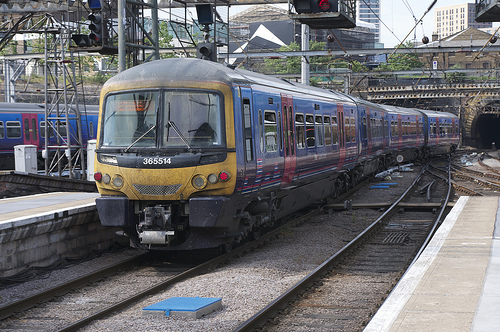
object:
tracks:
[260, 218, 438, 332]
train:
[93, 57, 463, 250]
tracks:
[338, 177, 440, 241]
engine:
[93, 57, 234, 251]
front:
[95, 57, 235, 251]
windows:
[101, 92, 222, 152]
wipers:
[123, 120, 195, 154]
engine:
[94, 57, 235, 243]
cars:
[93, 56, 463, 254]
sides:
[233, 80, 460, 195]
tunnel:
[459, 88, 500, 153]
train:
[87, 55, 465, 250]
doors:
[235, 86, 295, 194]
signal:
[288, 1, 356, 29]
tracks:
[74, 254, 377, 305]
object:
[142, 296, 222, 318]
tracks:
[0, 256, 368, 313]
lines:
[234, 147, 356, 195]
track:
[126, 199, 363, 330]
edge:
[393, 195, 463, 328]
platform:
[368, 195, 500, 323]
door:
[239, 87, 256, 195]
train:
[81, 57, 461, 262]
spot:
[92, 282, 108, 306]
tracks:
[338, 165, 499, 197]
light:
[94, 171, 124, 187]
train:
[88, 56, 460, 258]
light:
[190, 170, 230, 190]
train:
[84, 57, 460, 252]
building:
[109, 0, 497, 57]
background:
[230, 2, 496, 66]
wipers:
[126, 101, 191, 149]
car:
[92, 57, 463, 250]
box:
[142, 297, 222, 319]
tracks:
[1, 248, 364, 332]